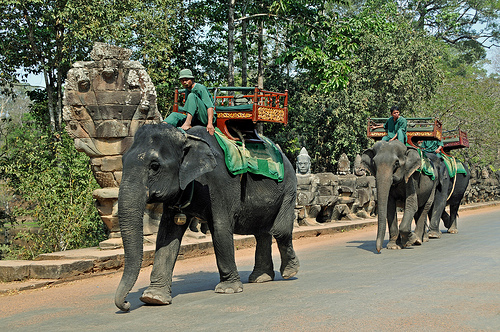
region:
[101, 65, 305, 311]
The elephant is carrying a man and his basket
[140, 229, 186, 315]
The leg of the elephant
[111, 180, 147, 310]
The trunk of the elephant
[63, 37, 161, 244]
A cement statue on the side of the road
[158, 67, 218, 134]
A man on top of the elephant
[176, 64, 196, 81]
The man is wearing a hat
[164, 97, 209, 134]
The man is wearing green pants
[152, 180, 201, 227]
The elephant is wearing a bell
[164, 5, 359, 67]
Te trees are tall with green leaves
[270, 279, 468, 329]
The street is made of asphalt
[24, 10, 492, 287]
elephant transports on the street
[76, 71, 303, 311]
this man is driving an elephant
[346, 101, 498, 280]
these are transport carriers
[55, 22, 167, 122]
a stonework in public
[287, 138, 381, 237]
public statues along the street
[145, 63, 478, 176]
these elephant drivers are wearing green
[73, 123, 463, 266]
these elephants are colored grey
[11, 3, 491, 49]
lots of trees above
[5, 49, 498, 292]
a sunny day for riding an elephant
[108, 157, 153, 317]
an elephant's long trunk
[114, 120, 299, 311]
The large elephant looks very sad.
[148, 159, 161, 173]
The right eye of a giant elephant.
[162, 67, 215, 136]
A young man is on the back of an elephant.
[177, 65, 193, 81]
The young man is wearing a green hat.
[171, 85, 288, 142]
A wooden furniture like cart.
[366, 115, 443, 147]
The wooden cart in on the back of the elephant.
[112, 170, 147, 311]
The trunk of an adult elephant.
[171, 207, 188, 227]
A bell is around the elephant's neck.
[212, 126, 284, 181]
A green blanket on the elephant's back.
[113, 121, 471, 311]
Three elephants are walking in the street.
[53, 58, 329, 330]
the elephant on the road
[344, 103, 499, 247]
elephants on the road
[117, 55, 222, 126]
man riding on elephant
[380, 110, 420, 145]
man riding elephant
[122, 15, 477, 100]
trees behind the statues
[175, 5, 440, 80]
the trees with green leaves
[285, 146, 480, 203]
statues beside the road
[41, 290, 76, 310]
the road is dirty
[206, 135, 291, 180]
green blanket on elephant's back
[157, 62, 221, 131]
man dressed in green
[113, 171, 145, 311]
Trunk of an elephant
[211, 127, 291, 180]
Green blanket on elephant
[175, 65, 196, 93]
Man wearing a green hat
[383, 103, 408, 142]
Man wearing a green shirt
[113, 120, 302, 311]
Young elephant with green blanket on it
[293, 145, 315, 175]
Stone statue of a head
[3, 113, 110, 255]
Green trees near statue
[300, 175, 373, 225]
Wall made of several stones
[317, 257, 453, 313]
Road made of pavement with dirt on it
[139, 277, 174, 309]
Foot of an elephant